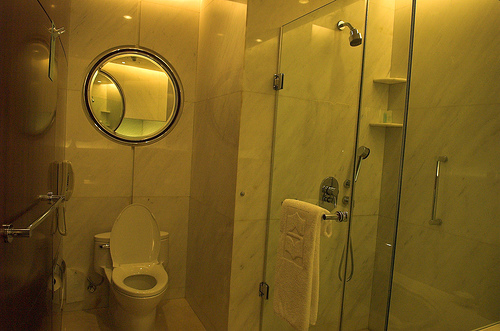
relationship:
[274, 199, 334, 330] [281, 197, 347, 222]
towel on rack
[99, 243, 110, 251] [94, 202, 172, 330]
handle on toilet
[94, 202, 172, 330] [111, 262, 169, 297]
toilet has a seat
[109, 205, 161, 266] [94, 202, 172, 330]
lid to toilet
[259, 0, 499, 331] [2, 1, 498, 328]
shower in bathroom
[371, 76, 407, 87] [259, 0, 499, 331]
shelf in shower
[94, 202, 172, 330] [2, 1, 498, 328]
toilet in bathroom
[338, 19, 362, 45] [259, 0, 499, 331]
shower head in shower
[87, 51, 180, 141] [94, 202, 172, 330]
mirror above toilet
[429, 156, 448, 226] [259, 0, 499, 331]
safety bar in shower